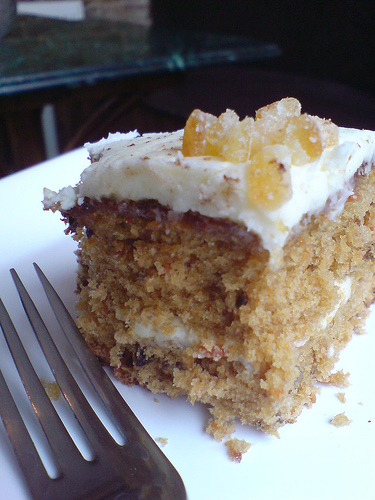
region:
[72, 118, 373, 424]
Piece of cake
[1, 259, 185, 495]
Silver fork next to a cake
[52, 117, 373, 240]
Thin layer ofwhite cake frosting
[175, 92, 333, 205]
Yellow sugar cake topping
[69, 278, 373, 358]
Midlayer frosting of cake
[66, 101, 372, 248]
White cake frosting and yellow topping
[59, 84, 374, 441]
Cake with white and yellow topping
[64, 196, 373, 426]
Yellow/brown cake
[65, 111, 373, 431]
Carrot cake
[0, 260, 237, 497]
Fork next to a cake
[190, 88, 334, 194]
fruit on the cake.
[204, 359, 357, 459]
crumbs on the plate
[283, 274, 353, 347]
white frosting between the cake.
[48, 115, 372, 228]
white frosting on the cake.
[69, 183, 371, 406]
the cake is brown.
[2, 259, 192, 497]
fork on the plate.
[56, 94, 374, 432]
cake on the plate.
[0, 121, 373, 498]
the plate is white.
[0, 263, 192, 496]
the fork is silver.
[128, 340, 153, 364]
raisins in the cake.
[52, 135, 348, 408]
One piece of cake is in plate.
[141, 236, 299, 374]
Cake is brown color.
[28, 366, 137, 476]
Fork is besides the cake.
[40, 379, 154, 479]
Fork is silver color.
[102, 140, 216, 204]
Cream is white color.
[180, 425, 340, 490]
Plate is white color.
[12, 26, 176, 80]
Table is black color.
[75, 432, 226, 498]
Fork is in plate.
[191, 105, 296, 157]
Topping is brown color.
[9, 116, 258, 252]
One fork is in plate.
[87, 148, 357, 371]
this is a cake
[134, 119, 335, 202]
the cake has a cream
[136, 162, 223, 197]
the cream is white in color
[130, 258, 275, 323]
the cake is brown in color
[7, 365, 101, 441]
this is a fork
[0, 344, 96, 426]
the fork is metallic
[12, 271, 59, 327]
the fork is sharp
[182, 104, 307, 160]
the cream is yellow in color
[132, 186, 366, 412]
the cake is big in size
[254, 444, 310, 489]
the table is white in color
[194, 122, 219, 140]
edge of a potato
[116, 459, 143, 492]
part of a spoon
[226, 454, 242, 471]
crunch of a cake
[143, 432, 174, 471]
edge of a fork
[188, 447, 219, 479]
part of a table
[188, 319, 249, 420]
edge of a cake